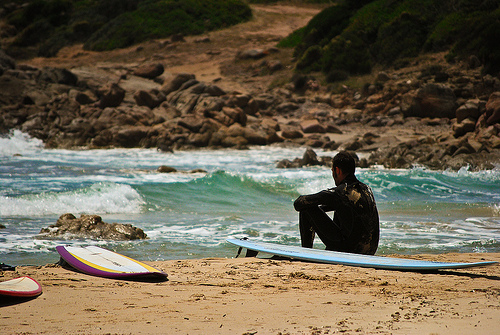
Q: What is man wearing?
A: Wetsuit.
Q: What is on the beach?
A: Surfboards.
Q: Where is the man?
A: Beach.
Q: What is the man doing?
A: Sitting on beach.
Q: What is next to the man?
A: Surfboard.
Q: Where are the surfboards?
A: Beach.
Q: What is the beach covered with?
A: Sand.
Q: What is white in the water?
A: Cresting wave.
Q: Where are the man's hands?
A: On knees.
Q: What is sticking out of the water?
A: Rocks.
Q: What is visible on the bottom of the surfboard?
A: Fin.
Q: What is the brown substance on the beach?
A: Sand.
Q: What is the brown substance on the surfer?
A: Sand.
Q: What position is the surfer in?
A: Sitting.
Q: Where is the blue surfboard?
A: Beside surfer.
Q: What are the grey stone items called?
A: Rocks.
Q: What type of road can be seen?
A: Dirt.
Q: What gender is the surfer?
A: Male.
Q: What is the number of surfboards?
A: 3.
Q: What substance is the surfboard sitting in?
A: Sand.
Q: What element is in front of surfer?
A: Water.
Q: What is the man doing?
A: Sitting on the beach.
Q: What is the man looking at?
A: The water.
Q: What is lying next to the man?
A: A surfboard.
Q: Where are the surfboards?
A: On the sand.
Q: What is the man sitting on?
A: Sand.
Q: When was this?
A: Daytime.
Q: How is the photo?
A: Clear.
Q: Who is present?
A: A man.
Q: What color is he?
A: White.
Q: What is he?
A: A surfer.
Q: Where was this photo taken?
A: On a beach.